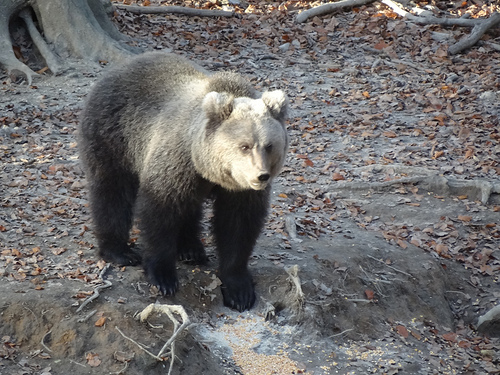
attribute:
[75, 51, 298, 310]
bear — black, brown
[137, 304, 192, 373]
stick — brown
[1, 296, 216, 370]
ground — brown